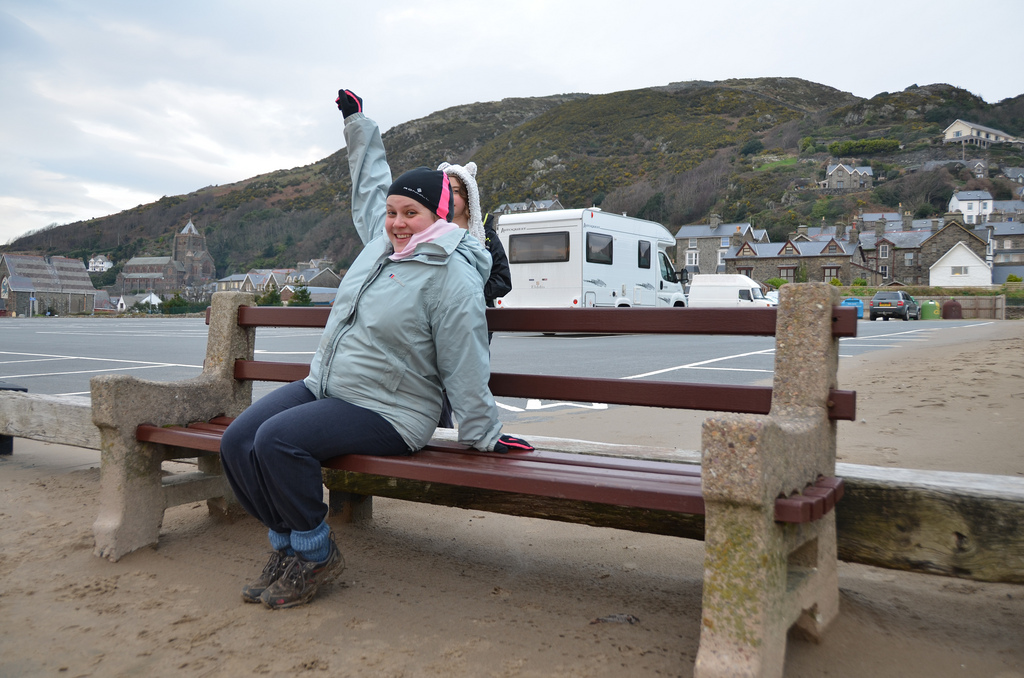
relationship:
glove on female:
[324, 76, 414, 127] [213, 87, 528, 607]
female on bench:
[213, 87, 528, 607] [102, 279, 862, 647]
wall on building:
[916, 218, 989, 291] [716, 231, 885, 285]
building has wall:
[728, 232, 885, 299] [751, 258, 781, 288]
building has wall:
[945, 117, 1018, 152] [939, 109, 1013, 153]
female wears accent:
[213, 87, 528, 607] [386, 168, 454, 221]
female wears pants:
[213, 87, 528, 607] [198, 372, 396, 524]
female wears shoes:
[213, 87, 528, 607] [219, 528, 380, 634]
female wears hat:
[213, 87, 528, 607] [433, 155, 492, 253]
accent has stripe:
[386, 168, 454, 221] [432, 159, 453, 229]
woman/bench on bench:
[89, 168, 867, 659] [88, 282, 856, 675]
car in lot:
[869, 288, 923, 320] [0, 249, 927, 524]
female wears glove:
[213, 87, 528, 607] [309, 68, 385, 158]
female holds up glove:
[213, 87, 528, 607] [336, 89, 368, 119]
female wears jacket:
[213, 87, 528, 607] [249, 109, 545, 475]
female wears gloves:
[213, 87, 528, 607] [327, 76, 366, 122]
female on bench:
[213, 87, 528, 607] [88, 282, 856, 675]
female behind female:
[213, 87, 528, 607] [213, 87, 528, 607]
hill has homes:
[468, 26, 965, 303] [649, 128, 1019, 291]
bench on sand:
[88, 282, 856, 675] [7, 468, 1020, 674]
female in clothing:
[208, 86, 534, 618] [218, 220, 528, 603]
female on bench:
[213, 87, 528, 607] [92, 259, 871, 664]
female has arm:
[213, 87, 528, 607] [294, 82, 411, 248]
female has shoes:
[213, 87, 528, 607] [251, 520, 356, 607]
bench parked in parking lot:
[485, 208, 682, 309] [4, 308, 985, 404]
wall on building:
[487, 212, 624, 318] [442, 161, 715, 363]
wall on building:
[698, 242, 717, 271] [680, 212, 870, 280]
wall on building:
[727, 255, 797, 263] [417, 87, 668, 323]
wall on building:
[923, 240, 946, 256] [417, 87, 668, 323]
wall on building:
[972, 271, 991, 281] [417, 87, 668, 323]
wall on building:
[817, 259, 849, 263] [417, 87, 668, 323]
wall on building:
[968, 237, 976, 247] [417, 87, 668, 323]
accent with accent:
[386, 168, 454, 221] [408, 156, 456, 217]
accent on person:
[386, 168, 454, 221] [222, 79, 495, 617]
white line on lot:
[27, 315, 146, 379] [8, 294, 987, 433]